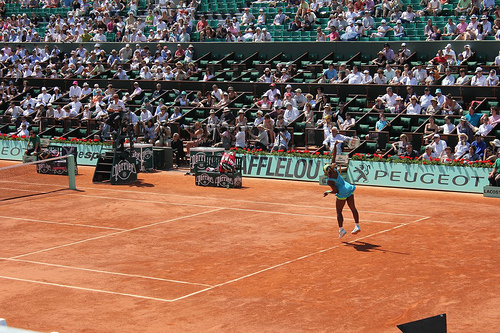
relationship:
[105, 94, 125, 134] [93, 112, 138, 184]
official sitting on green stand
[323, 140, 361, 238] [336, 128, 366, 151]
athlete swinging racket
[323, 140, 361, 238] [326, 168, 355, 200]
athlete wearing dress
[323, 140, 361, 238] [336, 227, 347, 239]
athlete wearing shoe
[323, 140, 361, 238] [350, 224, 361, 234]
athlete wearing shoe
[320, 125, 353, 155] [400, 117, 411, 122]
fan in seat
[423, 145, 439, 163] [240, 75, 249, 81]
fan in seat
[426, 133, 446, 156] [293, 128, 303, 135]
fan in seat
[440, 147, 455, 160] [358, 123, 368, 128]
fan in seat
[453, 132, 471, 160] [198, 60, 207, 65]
fan in seat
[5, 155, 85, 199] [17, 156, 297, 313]
net in court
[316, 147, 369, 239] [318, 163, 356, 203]
athlete in a dress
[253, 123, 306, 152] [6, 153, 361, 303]
person watching match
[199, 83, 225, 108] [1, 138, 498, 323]
person watching match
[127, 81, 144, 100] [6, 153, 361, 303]
person watching match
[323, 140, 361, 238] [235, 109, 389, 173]
athlete hitting ball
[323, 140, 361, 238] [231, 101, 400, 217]
athlete jumping in air